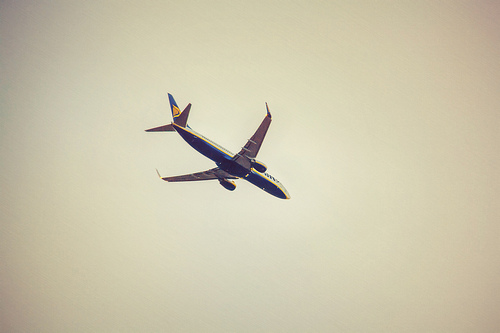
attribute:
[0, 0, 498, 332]
sky — cloudy, grey, above, gray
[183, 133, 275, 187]
fuselage — blue, yellow, painted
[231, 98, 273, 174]
right wing — plane's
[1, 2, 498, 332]
cloudy sky — small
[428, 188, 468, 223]
sky — cloudy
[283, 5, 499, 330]
sky — cloudy